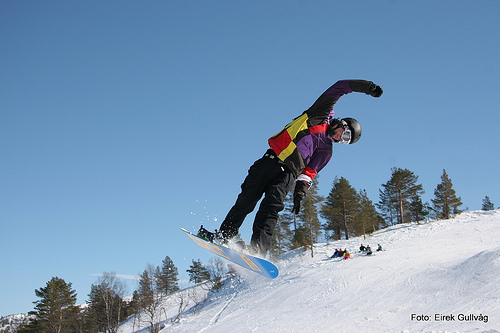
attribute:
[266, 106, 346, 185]
jacket — ck, red, yellow, purple, and whit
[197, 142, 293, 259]
pants — black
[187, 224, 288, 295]
board — blue and yellow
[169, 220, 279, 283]
snow board — blue, yellow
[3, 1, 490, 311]
sky — crystal blue, clear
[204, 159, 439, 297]
pants — black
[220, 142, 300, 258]
pants — black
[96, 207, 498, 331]
snow — white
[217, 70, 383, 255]
person — Athletic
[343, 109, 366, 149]
helmet — black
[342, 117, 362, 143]
helmet — black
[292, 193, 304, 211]
hand — gloved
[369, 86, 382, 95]
hand — gloved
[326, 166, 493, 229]
trees — Green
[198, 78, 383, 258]
person — athletic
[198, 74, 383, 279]
person — Athletic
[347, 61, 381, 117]
gloves — black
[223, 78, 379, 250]
coat — black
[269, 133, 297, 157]
block — multi colored